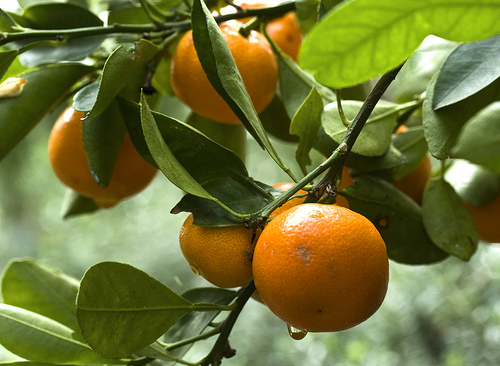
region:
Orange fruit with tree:
[36, 1, 473, 348]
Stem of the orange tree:
[308, 80, 402, 142]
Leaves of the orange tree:
[22, 258, 155, 332]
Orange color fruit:
[286, 230, 368, 295]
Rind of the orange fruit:
[293, 267, 344, 310]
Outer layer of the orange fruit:
[278, 223, 371, 311]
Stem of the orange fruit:
[240, 23, 252, 38]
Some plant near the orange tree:
[408, 287, 488, 343]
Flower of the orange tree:
[0, 72, 32, 99]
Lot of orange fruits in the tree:
[31, 17, 461, 347]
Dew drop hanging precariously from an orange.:
[248, 199, 393, 344]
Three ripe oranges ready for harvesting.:
[176, 176, 393, 331]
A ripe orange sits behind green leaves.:
[44, 56, 166, 210]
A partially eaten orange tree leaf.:
[98, 35, 160, 76]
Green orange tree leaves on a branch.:
[1, 284, 248, 364]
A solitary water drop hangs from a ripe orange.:
[250, 201, 390, 341]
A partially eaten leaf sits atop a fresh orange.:
[169, 183, 256, 289]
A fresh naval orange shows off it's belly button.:
[177, 213, 264, 286]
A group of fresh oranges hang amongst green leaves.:
[47, 16, 391, 341]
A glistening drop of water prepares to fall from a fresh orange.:
[249, 200, 391, 341]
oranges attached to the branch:
[205, 160, 398, 327]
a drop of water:
[260, 315, 321, 360]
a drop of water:
[285, 303, 330, 354]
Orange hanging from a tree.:
[252, 178, 396, 330]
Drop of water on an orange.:
[284, 323, 309, 343]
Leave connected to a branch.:
[59, 250, 244, 357]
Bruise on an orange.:
[290, 243, 313, 265]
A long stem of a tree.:
[325, 52, 400, 209]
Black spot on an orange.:
[314, 305, 324, 315]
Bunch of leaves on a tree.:
[419, 50, 495, 161]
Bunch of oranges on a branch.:
[147, 166, 419, 351]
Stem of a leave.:
[70, 300, 203, 322]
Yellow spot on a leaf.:
[1, 71, 37, 96]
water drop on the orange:
[279, 305, 312, 344]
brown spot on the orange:
[308, 293, 331, 320]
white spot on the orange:
[298, 244, 321, 269]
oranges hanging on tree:
[4, 7, 498, 355]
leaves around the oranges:
[2, 0, 497, 362]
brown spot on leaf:
[367, 211, 401, 236]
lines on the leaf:
[307, 5, 418, 84]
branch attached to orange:
[311, 166, 340, 210]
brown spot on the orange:
[239, 237, 252, 267]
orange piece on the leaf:
[2, 72, 30, 106]